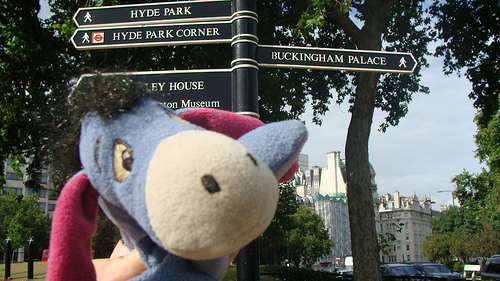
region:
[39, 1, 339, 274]
a stuffed animal outside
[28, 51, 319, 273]
a stuffed animal being held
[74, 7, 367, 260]
a pole with signs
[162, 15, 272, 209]
a metal pole with signs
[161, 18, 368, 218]
a pole with street signs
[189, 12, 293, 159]
a metal pole with street signs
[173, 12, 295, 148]
signs on a black pole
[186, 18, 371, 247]
signs on a black metal pole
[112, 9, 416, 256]
street signs on a black pole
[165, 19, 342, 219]
street signs stacked up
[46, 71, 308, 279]
Stuffed Eeyore toy.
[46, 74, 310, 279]
Hand holding up an Eeyore doll.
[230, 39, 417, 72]
Sign pointing the Buckingham Palace.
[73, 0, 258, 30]
Sign pointing to Hyde Park.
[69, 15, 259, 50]
Sign pointing to Hyde Park Corner.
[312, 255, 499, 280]
Cars to the right of the park.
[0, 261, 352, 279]
The grassy area of the park.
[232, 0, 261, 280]
Pole that the signs are on.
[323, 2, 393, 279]
Trunk of a tree.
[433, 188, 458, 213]
Streetlight behind the trees.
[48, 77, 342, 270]
eeyore puppet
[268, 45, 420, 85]
street sign showing the way to Buckingham palace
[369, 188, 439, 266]
building in the distance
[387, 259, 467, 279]
cars parked along the street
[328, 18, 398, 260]
tree behind the street sign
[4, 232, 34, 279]
two black poles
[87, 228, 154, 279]
hand holding the puppet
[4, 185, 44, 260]
tree in the park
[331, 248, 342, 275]
road sign in the distance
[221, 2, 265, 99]
pole with street signs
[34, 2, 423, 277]
Eeyore flying through London England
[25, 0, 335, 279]
Pooh Corner comes to Hyde Park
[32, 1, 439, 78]
Hyde Park this way, Buckingham Palace that way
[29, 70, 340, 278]
Eeyore is far from Pooh Corner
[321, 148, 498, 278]
View of English Architecture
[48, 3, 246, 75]
Hyde Park here we come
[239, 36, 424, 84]
Sign to Buckingham Palace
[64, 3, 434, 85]
Buckingham Palace to the right, Hyde Park to the left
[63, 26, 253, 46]
SIgn for Hyde Park Corner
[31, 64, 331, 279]
Stuffed Eeyore Doll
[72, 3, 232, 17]
The sign that reads Hyde Park.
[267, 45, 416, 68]
The sign that reads Buckingham Palace.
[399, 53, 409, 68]
The person emblem on the Buckingham Palace sign.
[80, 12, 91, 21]
The person emblem on the Hyde Park sign.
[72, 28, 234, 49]
The sign that reads Hyde Park Corner.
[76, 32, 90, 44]
The person emblem on the Hyde Park Corner sign.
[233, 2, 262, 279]
The pole the signs are mounted on.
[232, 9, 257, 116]
The white stripes on the pole.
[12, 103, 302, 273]
The pink ears of the stuff animal.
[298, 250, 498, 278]
The cars on the right.